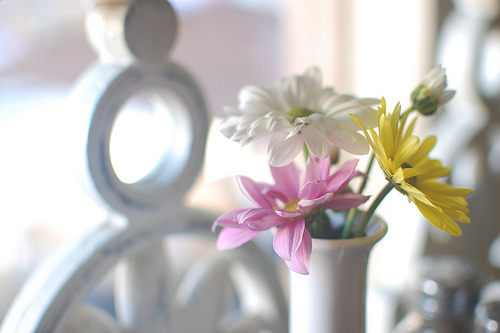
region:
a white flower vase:
[311, 274, 357, 314]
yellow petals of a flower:
[426, 190, 452, 222]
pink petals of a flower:
[282, 230, 300, 255]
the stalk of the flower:
[370, 189, 377, 215]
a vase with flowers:
[246, 76, 407, 325]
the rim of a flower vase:
[332, 238, 346, 247]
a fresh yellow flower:
[373, 113, 444, 185]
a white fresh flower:
[276, 86, 333, 143]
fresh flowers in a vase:
[254, 67, 382, 319]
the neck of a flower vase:
[293, 280, 373, 318]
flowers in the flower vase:
[243, 63, 474, 263]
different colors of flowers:
[236, 68, 461, 255]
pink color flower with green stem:
[238, 157, 355, 240]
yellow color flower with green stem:
[364, 107, 444, 231]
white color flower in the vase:
[260, 61, 376, 155]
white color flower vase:
[274, 210, 406, 331]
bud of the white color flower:
[407, 64, 460, 124]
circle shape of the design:
[80, 54, 196, 211]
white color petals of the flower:
[252, 102, 284, 150]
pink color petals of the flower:
[247, 194, 290, 234]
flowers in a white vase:
[212, 48, 473, 332]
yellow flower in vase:
[362, 103, 464, 245]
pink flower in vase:
[225, 150, 357, 272]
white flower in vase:
[212, 63, 369, 159]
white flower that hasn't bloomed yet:
[408, 63, 458, 116]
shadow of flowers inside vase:
[313, 207, 358, 240]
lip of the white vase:
[281, 193, 384, 250]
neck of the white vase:
[281, 253, 360, 332]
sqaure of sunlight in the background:
[4, 73, 241, 231]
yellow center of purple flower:
[278, 195, 300, 212]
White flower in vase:
[228, 58, 374, 163]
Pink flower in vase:
[216, 139, 350, 273]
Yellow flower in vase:
[368, 114, 455, 239]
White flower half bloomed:
[406, 48, 468, 133]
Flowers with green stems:
[262, 95, 409, 238]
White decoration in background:
[26, 19, 294, 331]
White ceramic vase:
[272, 198, 394, 329]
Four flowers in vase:
[240, 78, 415, 255]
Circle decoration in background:
[57, 2, 217, 221]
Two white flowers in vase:
[250, 55, 451, 159]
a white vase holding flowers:
[269, 206, 389, 331]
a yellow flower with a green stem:
[348, 94, 472, 243]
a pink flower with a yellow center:
[214, 155, 371, 278]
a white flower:
[210, 66, 383, 161]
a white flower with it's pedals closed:
[405, 62, 458, 116]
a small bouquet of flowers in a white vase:
[212, 59, 472, 331]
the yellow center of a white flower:
[283, 105, 318, 119]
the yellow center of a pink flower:
[279, 197, 301, 214]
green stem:
[358, 172, 391, 236]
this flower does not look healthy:
[413, 59, 455, 121]